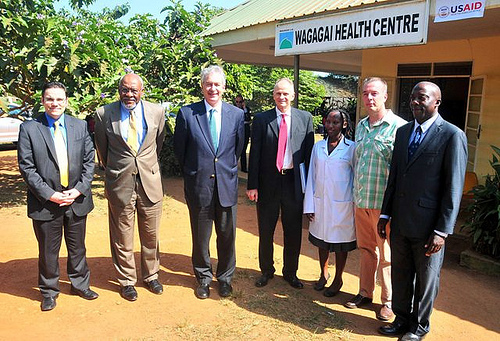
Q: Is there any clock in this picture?
A: No, there are no clocks.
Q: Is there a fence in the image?
A: No, there are no fences.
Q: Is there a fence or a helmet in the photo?
A: No, there are no fences or helmets.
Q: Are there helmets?
A: No, there are no helmets.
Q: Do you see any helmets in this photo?
A: No, there are no helmets.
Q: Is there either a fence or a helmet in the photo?
A: No, there are no helmets or fences.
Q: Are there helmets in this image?
A: No, there are no helmets.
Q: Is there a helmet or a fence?
A: No, there are no helmets or fences.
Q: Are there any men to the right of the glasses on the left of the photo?
A: Yes, there is a man to the right of the glasses.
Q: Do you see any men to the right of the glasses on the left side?
A: Yes, there is a man to the right of the glasses.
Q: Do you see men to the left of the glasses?
A: No, the man is to the right of the glasses.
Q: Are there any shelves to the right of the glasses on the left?
A: No, there is a man to the right of the glasses.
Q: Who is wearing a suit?
A: The man is wearing a suit.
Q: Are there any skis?
A: No, there are no skis.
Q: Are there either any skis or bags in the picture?
A: No, there are no skis or bags.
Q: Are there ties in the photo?
A: Yes, there is a tie.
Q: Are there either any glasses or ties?
A: Yes, there is a tie.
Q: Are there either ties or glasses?
A: Yes, there is a tie.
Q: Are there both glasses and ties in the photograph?
A: Yes, there are both a tie and glasses.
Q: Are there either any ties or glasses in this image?
A: Yes, there is a tie.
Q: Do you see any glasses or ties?
A: Yes, there is a tie.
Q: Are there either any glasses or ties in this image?
A: Yes, there is a tie.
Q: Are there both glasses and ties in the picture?
A: Yes, there are both a tie and glasses.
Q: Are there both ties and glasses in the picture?
A: Yes, there are both a tie and glasses.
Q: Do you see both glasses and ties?
A: Yes, there are both a tie and glasses.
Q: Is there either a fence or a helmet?
A: No, there are no helmets or fences.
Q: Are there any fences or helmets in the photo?
A: No, there are no helmets or fences.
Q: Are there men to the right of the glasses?
A: Yes, there is a man to the right of the glasses.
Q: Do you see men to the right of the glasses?
A: Yes, there is a man to the right of the glasses.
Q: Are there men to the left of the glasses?
A: No, the man is to the right of the glasses.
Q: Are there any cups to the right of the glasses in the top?
A: No, there is a man to the right of the glasses.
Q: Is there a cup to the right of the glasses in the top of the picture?
A: No, there is a man to the right of the glasses.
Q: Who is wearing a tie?
A: The man is wearing a tie.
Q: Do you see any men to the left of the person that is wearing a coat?
A: Yes, there is a man to the left of the person.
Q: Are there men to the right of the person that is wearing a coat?
A: No, the man is to the left of the person.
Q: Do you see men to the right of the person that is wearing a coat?
A: No, the man is to the left of the person.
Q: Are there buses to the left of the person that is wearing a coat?
A: No, there is a man to the left of the person.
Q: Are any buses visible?
A: No, there are no buses.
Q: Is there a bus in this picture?
A: No, there are no buses.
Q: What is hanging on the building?
A: The sign is hanging on the building.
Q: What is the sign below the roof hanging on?
A: The sign is hanging on the building.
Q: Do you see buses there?
A: No, there are no buses.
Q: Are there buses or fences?
A: No, there are no buses or fences.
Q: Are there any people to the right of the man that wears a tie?
A: Yes, there is a person to the right of the man.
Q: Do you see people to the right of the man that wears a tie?
A: Yes, there is a person to the right of the man.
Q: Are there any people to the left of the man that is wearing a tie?
A: No, the person is to the right of the man.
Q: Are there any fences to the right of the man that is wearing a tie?
A: No, there is a person to the right of the man.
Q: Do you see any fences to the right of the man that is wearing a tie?
A: No, there is a person to the right of the man.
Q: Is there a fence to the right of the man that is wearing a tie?
A: No, there is a person to the right of the man.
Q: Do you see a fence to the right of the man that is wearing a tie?
A: No, there is a person to the right of the man.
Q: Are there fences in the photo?
A: No, there are no fences.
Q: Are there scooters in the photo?
A: No, there are no scooters.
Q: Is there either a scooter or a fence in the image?
A: No, there are no scooters or fences.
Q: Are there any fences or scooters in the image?
A: No, there are no scooters or fences.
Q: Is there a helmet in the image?
A: No, there are no helmets.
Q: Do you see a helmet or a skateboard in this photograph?
A: No, there are no helmets or skateboards.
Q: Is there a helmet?
A: No, there are no helmets.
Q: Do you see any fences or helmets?
A: No, there are no helmets or fences.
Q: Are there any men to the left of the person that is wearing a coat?
A: Yes, there is a man to the left of the person.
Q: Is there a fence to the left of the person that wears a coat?
A: No, there is a man to the left of the person.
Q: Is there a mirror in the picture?
A: No, there are no mirrors.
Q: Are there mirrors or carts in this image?
A: No, there are no mirrors or carts.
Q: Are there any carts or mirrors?
A: No, there are no mirrors or carts.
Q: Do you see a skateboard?
A: No, there are no skateboards.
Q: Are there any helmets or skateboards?
A: No, there are no skateboards or helmets.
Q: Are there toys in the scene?
A: No, there are no toys.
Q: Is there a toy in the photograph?
A: No, there are no toys.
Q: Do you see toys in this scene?
A: No, there are no toys.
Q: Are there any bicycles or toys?
A: No, there are no toys or bicycles.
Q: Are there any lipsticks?
A: No, there are no lipsticks.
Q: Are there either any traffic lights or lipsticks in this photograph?
A: No, there are no lipsticks or traffic lights.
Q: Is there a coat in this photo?
A: Yes, there is a coat.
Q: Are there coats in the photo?
A: Yes, there is a coat.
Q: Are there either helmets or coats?
A: Yes, there is a coat.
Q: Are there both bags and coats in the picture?
A: No, there is a coat but no bags.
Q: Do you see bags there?
A: No, there are no bags.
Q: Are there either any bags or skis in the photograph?
A: No, there are no bags or skis.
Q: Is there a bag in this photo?
A: No, there are no bags.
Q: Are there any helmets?
A: No, there are no helmets.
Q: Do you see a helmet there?
A: No, there are no helmets.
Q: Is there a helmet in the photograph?
A: No, there are no helmets.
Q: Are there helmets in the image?
A: No, there are no helmets.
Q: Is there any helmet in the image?
A: No, there are no helmets.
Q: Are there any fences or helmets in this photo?
A: No, there are no helmets or fences.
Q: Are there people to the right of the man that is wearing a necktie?
A: Yes, there is a person to the right of the man.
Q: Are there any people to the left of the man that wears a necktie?
A: No, the person is to the right of the man.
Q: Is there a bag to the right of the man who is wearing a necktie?
A: No, there is a person to the right of the man.